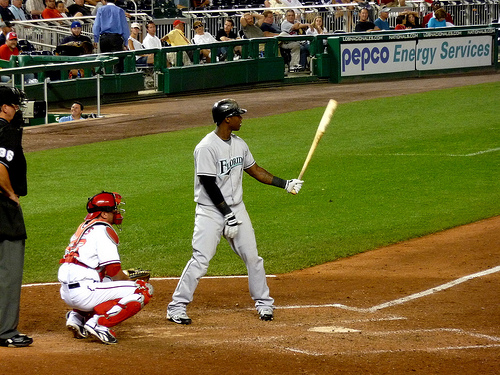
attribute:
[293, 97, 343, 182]
baseball bat — wooden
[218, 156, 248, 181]
marlins logo — baseball, florida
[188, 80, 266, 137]
helmet — black, white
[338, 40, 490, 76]
sign — blue, white, adverisement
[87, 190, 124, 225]
helmet — red, catcher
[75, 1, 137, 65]
man shirt — blue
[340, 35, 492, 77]
banner — stadium advertising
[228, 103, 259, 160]
wall — white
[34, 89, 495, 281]
grass — short, bright green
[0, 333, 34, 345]
shoe — black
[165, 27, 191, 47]
shirt — yellow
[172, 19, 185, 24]
hat — red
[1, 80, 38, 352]
umpire — black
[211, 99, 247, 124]
baseball helmet — dark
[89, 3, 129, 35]
shirt — blue, long sleeve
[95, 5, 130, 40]
shirt — blue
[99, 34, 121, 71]
pants — black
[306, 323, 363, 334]
plate — home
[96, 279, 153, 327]
knee guards — red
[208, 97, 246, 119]
helmet — hard, black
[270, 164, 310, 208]
hand — one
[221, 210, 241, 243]
baseball glove — black, white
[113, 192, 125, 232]
mask — red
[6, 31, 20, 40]
hat — red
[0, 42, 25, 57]
shirt — red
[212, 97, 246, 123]
baseball cap — black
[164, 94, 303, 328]
batter — baseball 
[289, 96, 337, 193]
bat — wooden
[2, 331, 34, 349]
dress shoes — white, black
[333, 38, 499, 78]
banner — advertisement 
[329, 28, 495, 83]
advertising — pepco energy services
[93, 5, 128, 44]
dress shirt — blue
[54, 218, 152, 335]
uniform — red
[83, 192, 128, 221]
mask — red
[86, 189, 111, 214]
helmet — black, red